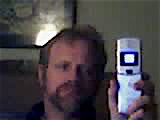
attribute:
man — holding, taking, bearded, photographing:
[24, 15, 134, 119]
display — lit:
[119, 49, 139, 68]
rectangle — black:
[118, 52, 139, 68]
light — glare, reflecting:
[122, 53, 138, 68]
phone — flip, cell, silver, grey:
[109, 33, 146, 115]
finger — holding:
[131, 75, 153, 113]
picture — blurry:
[0, 4, 82, 68]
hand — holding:
[105, 58, 158, 109]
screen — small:
[115, 49, 144, 71]